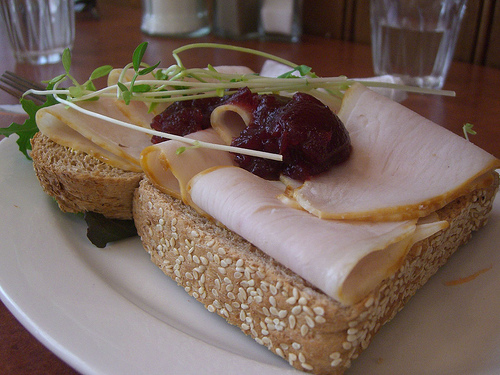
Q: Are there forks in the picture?
A: Yes, there is a fork.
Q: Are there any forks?
A: Yes, there is a fork.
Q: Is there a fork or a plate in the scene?
A: Yes, there is a fork.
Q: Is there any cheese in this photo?
A: No, there is no cheese.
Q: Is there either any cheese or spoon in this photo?
A: No, there are no cheese or spoons.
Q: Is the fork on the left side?
A: Yes, the fork is on the left of the image.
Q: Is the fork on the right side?
A: No, the fork is on the left of the image.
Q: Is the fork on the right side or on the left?
A: The fork is on the left of the image.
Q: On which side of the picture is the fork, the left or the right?
A: The fork is on the left of the image.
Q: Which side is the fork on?
A: The fork is on the left of the image.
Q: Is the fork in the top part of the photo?
A: Yes, the fork is in the top of the image.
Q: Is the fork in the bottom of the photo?
A: No, the fork is in the top of the image.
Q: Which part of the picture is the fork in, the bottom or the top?
A: The fork is in the top of the image.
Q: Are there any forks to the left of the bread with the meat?
A: Yes, there is a fork to the left of the bread.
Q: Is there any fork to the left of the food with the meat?
A: Yes, there is a fork to the left of the bread.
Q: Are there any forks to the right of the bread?
A: No, the fork is to the left of the bread.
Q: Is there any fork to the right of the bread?
A: No, the fork is to the left of the bread.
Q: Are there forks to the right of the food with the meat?
A: No, the fork is to the left of the bread.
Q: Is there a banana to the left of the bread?
A: No, there is a fork to the left of the bread.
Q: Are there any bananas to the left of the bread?
A: No, there is a fork to the left of the bread.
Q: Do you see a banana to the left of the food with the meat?
A: No, there is a fork to the left of the bread.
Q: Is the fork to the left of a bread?
A: Yes, the fork is to the left of a bread.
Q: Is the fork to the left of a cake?
A: No, the fork is to the left of a bread.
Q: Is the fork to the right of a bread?
A: No, the fork is to the left of a bread.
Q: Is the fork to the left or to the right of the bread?
A: The fork is to the left of the bread.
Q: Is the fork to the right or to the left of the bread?
A: The fork is to the left of the bread.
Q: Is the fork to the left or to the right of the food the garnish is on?
A: The fork is to the left of the bread.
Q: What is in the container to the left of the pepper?
A: The sugar is in the container.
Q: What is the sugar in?
A: The sugar is in the container.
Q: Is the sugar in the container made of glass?
A: Yes, the sugar is in the container.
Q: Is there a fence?
A: No, there are no fences.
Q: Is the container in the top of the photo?
A: Yes, the container is in the top of the image.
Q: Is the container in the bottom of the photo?
A: No, the container is in the top of the image.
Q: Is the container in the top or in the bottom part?
A: The container is in the top of the image.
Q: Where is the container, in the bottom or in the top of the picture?
A: The container is in the top of the image.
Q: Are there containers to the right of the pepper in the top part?
A: Yes, there is a container to the right of the pepper.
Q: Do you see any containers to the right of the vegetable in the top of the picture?
A: Yes, there is a container to the right of the pepper.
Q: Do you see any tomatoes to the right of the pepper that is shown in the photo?
A: No, there is a container to the right of the pepper.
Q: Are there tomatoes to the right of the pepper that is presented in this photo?
A: No, there is a container to the right of the pepper.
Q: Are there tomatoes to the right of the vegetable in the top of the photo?
A: No, there is a container to the right of the pepper.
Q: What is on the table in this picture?
A: The water is on the table.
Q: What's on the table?
A: The water is on the table.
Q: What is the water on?
A: The water is on the table.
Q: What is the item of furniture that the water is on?
A: The piece of furniture is a table.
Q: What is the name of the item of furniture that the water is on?
A: The piece of furniture is a table.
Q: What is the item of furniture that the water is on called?
A: The piece of furniture is a table.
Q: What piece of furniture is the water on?
A: The water is on the table.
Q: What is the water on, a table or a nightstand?
A: The water is on a table.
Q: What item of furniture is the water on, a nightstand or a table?
A: The water is on a table.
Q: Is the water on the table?
A: Yes, the water is on the table.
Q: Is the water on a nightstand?
A: No, the water is on the table.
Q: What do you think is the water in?
A: The water is in the container.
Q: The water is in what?
A: The water is in the container.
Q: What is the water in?
A: The water is in the container.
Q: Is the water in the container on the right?
A: Yes, the water is in the container.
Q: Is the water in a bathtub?
A: No, the water is in the container.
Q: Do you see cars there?
A: No, there are no cars.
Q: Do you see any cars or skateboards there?
A: No, there are no cars or skateboards.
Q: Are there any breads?
A: Yes, there is a bread.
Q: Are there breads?
A: Yes, there is a bread.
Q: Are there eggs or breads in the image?
A: Yes, there is a bread.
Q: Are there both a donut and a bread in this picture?
A: No, there is a bread but no donuts.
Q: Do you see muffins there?
A: No, there are no muffins.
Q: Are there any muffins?
A: No, there are no muffins.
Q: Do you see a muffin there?
A: No, there are no muffins.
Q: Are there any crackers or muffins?
A: No, there are no muffins or crackers.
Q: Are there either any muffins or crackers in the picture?
A: No, there are no muffins or crackers.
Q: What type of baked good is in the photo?
A: The baked good is a bread.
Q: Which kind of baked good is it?
A: The food is a bread.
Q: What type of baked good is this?
A: That is a bread.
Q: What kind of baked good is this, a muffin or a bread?
A: That is a bread.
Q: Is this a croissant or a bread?
A: This is a bread.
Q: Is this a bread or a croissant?
A: This is a bread.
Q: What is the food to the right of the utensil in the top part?
A: The food is a bread.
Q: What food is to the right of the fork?
A: The food is a bread.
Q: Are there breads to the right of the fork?
A: Yes, there is a bread to the right of the fork.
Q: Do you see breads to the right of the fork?
A: Yes, there is a bread to the right of the fork.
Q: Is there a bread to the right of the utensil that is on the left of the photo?
A: Yes, there is a bread to the right of the fork.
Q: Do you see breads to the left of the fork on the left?
A: No, the bread is to the right of the fork.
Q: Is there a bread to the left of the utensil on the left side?
A: No, the bread is to the right of the fork.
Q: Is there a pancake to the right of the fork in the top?
A: No, there is a bread to the right of the fork.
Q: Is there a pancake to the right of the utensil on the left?
A: No, there is a bread to the right of the fork.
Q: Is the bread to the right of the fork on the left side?
A: Yes, the bread is to the right of the fork.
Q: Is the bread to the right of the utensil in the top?
A: Yes, the bread is to the right of the fork.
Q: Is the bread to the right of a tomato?
A: No, the bread is to the right of the fork.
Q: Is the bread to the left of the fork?
A: No, the bread is to the right of the fork.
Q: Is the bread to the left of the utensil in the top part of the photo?
A: No, the bread is to the right of the fork.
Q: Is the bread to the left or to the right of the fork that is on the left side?
A: The bread is to the right of the fork.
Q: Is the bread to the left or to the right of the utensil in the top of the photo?
A: The bread is to the right of the fork.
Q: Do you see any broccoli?
A: No, there is no broccoli.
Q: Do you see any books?
A: No, there are no books.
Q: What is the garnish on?
A: The garnish is on the bread.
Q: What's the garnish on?
A: The garnish is on the bread.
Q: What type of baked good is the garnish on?
A: The garnish is on the bread.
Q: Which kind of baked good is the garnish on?
A: The garnish is on the bread.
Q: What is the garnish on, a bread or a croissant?
A: The garnish is on a bread.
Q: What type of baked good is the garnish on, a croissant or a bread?
A: The garnish is on a bread.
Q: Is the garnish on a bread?
A: Yes, the garnish is on a bread.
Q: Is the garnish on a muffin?
A: No, the garnish is on a bread.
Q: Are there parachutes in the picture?
A: No, there are no parachutes.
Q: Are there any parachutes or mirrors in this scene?
A: No, there are no parachutes or mirrors.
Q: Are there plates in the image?
A: Yes, there is a plate.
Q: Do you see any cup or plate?
A: Yes, there is a plate.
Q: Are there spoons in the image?
A: No, there are no spoons.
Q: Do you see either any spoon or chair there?
A: No, there are no spoons or chairs.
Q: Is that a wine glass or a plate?
A: That is a plate.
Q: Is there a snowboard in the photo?
A: No, there are no snowboards.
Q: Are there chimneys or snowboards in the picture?
A: No, there are no snowboards or chimneys.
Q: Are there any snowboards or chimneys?
A: No, there are no snowboards or chimneys.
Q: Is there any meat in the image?
A: Yes, there is meat.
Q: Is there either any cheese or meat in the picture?
A: Yes, there is meat.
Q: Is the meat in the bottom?
A: Yes, the meat is in the bottom of the image.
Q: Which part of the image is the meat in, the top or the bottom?
A: The meat is in the bottom of the image.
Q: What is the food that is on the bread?
A: The food is meat.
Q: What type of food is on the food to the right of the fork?
A: The food is meat.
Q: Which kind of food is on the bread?
A: The food is meat.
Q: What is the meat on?
A: The meat is on the bread.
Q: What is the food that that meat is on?
A: The food is a bread.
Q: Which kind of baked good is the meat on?
A: The meat is on the bread.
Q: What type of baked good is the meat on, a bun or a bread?
A: The meat is on a bread.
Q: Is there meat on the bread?
A: Yes, there is meat on the bread.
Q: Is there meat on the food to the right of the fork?
A: Yes, there is meat on the bread.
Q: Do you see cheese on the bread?
A: No, there is meat on the bread.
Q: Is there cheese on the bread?
A: No, there is meat on the bread.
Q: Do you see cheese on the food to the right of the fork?
A: No, there is meat on the bread.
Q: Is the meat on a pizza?
A: No, the meat is on the bread.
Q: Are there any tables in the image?
A: Yes, there is a table.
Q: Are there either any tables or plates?
A: Yes, there is a table.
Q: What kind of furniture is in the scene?
A: The furniture is a table.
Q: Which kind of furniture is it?
A: The piece of furniture is a table.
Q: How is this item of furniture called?
A: This is a table.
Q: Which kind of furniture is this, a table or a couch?
A: This is a table.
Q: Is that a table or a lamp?
A: That is a table.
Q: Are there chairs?
A: No, there are no chairs.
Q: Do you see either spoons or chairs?
A: No, there are no chairs or spoons.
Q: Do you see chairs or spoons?
A: No, there are no chairs or spoons.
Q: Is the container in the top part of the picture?
A: Yes, the container is in the top of the image.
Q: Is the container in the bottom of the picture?
A: No, the container is in the top of the image.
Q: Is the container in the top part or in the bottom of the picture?
A: The container is in the top of the image.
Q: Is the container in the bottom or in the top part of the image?
A: The container is in the top of the image.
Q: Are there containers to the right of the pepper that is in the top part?
A: Yes, there is a container to the right of the pepper.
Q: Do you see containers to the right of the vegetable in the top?
A: Yes, there is a container to the right of the pepper.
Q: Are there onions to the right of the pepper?
A: No, there is a container to the right of the pepper.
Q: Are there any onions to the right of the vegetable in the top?
A: No, there is a container to the right of the pepper.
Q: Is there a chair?
A: No, there are no chairs.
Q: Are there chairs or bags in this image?
A: No, there are no chairs or bags.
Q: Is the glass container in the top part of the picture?
A: Yes, the container is in the top of the image.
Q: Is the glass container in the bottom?
A: No, the container is in the top of the image.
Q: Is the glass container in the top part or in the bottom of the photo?
A: The container is in the top of the image.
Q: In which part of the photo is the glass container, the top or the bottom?
A: The container is in the top of the image.